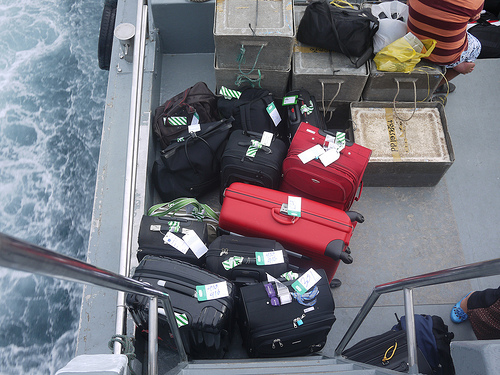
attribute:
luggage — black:
[219, 126, 286, 202]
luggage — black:
[221, 85, 287, 139]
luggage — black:
[234, 269, 341, 353]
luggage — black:
[138, 211, 208, 266]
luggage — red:
[280, 122, 371, 210]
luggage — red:
[216, 179, 365, 289]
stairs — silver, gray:
[0, 227, 499, 372]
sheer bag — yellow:
[370, 31, 436, 73]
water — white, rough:
[1, 1, 108, 375]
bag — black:
[295, 0, 379, 68]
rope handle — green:
[146, 197, 219, 224]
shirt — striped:
[407, 1, 483, 61]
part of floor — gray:
[163, 49, 499, 354]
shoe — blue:
[453, 293, 470, 325]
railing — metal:
[4, 214, 500, 375]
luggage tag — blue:
[253, 248, 287, 266]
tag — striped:
[337, 128, 345, 148]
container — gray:
[150, 3, 212, 55]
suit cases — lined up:
[126, 80, 372, 358]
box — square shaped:
[348, 97, 455, 189]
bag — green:
[145, 193, 220, 226]